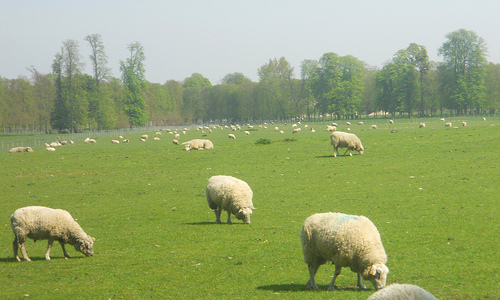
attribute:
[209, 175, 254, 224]
sheep — white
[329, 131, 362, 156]
sheep — white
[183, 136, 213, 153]
sheep — white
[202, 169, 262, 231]
sheep — white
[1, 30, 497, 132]
trees — green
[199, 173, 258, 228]
sheep — white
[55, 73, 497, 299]
field — green, grassy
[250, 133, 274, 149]
bush — small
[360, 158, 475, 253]
grass — green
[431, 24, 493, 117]
trees — green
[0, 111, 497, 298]
field — large, green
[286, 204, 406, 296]
sheep — white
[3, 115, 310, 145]
fence — light , grey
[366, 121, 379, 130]
sheep — white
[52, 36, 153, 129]
trees — green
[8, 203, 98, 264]
sheep — white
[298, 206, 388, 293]
sheep — white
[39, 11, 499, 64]
sky — grey